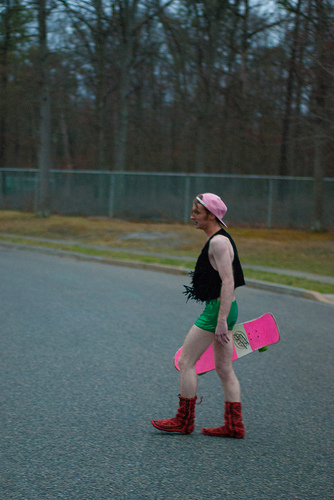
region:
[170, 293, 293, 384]
man carrying a bright pink skateboard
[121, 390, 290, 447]
man wearing red shoes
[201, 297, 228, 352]
man wearing bright green shorts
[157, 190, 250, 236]
man wearing a ball cap backwards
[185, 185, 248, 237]
ball cap is pink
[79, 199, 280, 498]
man is walking in the road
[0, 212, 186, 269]
sidewalk on side of road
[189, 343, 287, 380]
green wheels on the skateboard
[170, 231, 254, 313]
man wearing a black vest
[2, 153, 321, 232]
chain fence along the side of the trees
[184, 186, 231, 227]
a man wearing a pink cap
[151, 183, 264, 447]
man carrying a skateboard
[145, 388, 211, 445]
a red boot on a foot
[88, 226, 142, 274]
sidewalk on the edge of a street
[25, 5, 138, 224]
trees behind a fence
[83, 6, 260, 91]
lots of tree branches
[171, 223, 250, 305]
black vest with tassels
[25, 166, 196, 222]
fence at the edge of the woods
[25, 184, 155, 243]
fence at the edge of the grass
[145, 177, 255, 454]
man holding a skateboard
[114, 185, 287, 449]
man carrying a skateboard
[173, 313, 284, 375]
skateboard is bright pink and white, with a black design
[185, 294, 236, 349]
man is wearing high cut green shorts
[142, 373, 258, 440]
man is wearing red boots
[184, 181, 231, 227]
man is wearing a pink baseball cap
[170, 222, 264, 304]
man is wearing a black sleeveless top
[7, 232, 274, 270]
sidewalk beside the street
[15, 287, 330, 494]
man is standing in the street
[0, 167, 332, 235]
chain-link fence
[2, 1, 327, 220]
tall trees behind fence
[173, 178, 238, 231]
Man's head with pink hat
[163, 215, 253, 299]
Ripped black vest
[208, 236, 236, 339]
Extremely pale arm and hand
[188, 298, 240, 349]
Very short green shorts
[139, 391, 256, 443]
Red shoes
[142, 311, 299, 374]
Pink skateboard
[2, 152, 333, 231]
Fence in the backgrounf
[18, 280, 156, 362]
Part of the asphalt path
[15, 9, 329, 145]
Some blurry trees in the background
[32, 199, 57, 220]
Tree stump of blurry tree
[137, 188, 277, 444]
The man is girly.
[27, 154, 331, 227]
There is a fence in the background.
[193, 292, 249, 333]
The man is wearing tight shorts.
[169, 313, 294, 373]
The skateboard has a white line on it.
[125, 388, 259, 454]
Boots have no heels.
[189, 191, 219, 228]
Man has sideburns.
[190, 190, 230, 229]
Man is wearing pink ball cap.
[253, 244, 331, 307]
There is a sidewalk.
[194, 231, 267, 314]
The person wears a sleeveless jacket.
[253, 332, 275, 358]
Wheels of the skateboard are green.